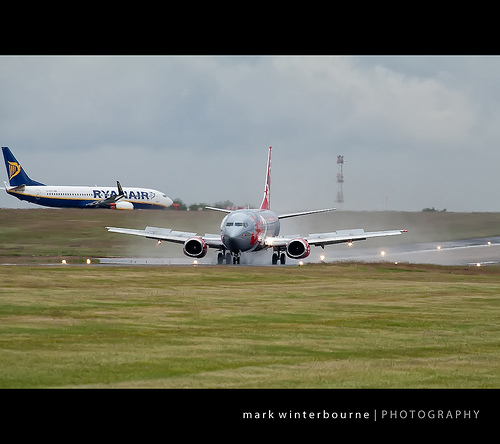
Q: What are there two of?
A: Planes.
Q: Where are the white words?
A: Under grass.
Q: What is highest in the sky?
A: White clouds.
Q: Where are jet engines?
A: Under plane wings.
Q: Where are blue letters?
A: White plane.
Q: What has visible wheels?
A: Silver plane.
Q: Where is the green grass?
A: Ground.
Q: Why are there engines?
A: Power the planes.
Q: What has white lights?
A: Runway.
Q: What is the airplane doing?
A: Landing.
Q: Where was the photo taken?
A: Airport.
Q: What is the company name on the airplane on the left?
A: RyanAir.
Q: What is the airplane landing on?
A: Runway.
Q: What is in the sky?
A: Clouds.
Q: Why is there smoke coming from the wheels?
A: Plane is landing.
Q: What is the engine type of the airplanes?
A: Jet.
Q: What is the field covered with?
A: Grass.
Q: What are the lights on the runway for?
A: Outlining the runway.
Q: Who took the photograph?
A: Mark Winterbourne.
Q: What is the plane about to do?
A: Take off.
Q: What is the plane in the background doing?
A: Landing on the runway.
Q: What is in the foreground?
A: Grass.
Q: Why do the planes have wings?
A: To be able to fly.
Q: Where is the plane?
A: On runway.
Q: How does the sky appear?
A: Cloudy.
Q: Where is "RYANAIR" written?
A: On side of the plane.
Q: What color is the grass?
A: Green.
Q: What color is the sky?
A: Blue and gray.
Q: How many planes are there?
A: Two.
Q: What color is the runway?
A: Gray.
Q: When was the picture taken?
A: Daytime.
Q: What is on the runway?
A: A plane.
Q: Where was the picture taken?
A: At an airfield.